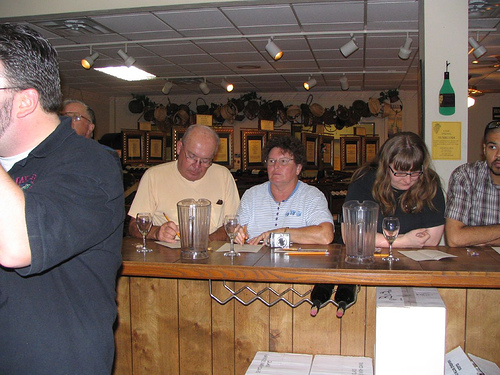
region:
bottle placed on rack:
[308, 283, 358, 319]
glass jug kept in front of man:
[178, 198, 214, 257]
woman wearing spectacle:
[264, 155, 293, 168]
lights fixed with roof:
[267, 41, 283, 58]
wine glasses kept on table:
[223, 214, 242, 256]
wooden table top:
[256, 255, 336, 281]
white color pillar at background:
[426, 39, 468, 167]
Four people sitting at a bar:
[124, 115, 497, 294]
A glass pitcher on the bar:
[170, 192, 219, 271]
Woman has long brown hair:
[346, 125, 441, 217]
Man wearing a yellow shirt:
[121, 119, 242, 242]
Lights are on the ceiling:
[72, 30, 488, 98]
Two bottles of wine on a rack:
[201, 278, 363, 322]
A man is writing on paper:
[124, 120, 244, 252]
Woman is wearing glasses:
[251, 130, 306, 187]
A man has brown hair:
[1, 16, 71, 120]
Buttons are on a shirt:
[267, 195, 286, 231]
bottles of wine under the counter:
[281, 286, 362, 329]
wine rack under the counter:
[196, 284, 300, 316]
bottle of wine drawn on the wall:
[423, 50, 461, 126]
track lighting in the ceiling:
[235, 34, 430, 64]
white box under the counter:
[360, 290, 456, 372]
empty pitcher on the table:
[178, 195, 212, 265]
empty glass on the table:
[219, 219, 240, 265]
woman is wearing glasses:
[258, 148, 293, 171]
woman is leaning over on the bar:
[350, 139, 455, 238]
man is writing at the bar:
[121, 112, 239, 239]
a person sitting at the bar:
[57, 90, 120, 174]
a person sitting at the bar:
[127, 116, 240, 241]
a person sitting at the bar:
[233, 138, 337, 252]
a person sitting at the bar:
[345, 130, 442, 252]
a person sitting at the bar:
[445, 120, 499, 249]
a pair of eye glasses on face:
[181, 150, 211, 165]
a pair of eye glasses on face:
[265, 153, 296, 169]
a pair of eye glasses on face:
[386, 162, 421, 180]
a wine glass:
[220, 215, 243, 253]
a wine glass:
[136, 212, 153, 251]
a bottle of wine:
[333, 284, 353, 321]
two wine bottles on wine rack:
[205, 275, 365, 320]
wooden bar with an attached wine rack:
[111, 232, 496, 373]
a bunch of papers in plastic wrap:
[370, 285, 446, 372]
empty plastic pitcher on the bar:
[175, 197, 214, 264]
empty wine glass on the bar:
[132, 210, 154, 255]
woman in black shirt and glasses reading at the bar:
[346, 122, 446, 248]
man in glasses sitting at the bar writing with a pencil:
[128, 120, 242, 250]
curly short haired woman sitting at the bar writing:
[230, 130, 337, 255]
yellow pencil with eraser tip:
[278, 248, 330, 257]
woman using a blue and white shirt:
[257, 140, 318, 245]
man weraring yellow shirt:
[165, 132, 220, 213]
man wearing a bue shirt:
[12, 105, 104, 320]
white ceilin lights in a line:
[68, 45, 388, 62]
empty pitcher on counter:
[168, 195, 223, 262]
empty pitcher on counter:
[159, 195, 217, 269]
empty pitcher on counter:
[165, 183, 217, 272]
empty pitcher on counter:
[157, 189, 222, 271]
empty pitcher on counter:
[157, 191, 226, 271]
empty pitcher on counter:
[168, 191, 222, 266]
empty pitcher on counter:
[166, 185, 223, 269]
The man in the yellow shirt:
[128, 126, 250, 248]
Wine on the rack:
[304, 281, 334, 316]